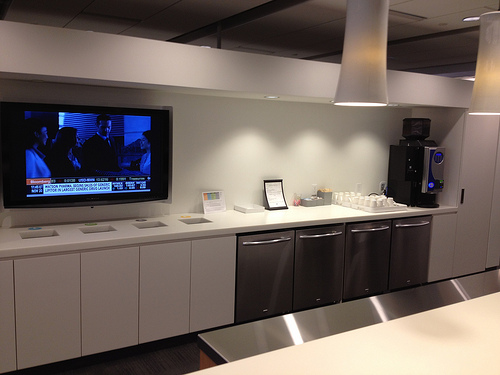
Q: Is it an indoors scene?
A: Yes, it is indoors.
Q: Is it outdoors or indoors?
A: It is indoors.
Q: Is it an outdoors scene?
A: No, it is indoors.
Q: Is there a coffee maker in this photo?
A: Yes, there is a coffee maker.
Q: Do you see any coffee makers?
A: Yes, there is a coffee maker.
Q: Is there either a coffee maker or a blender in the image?
A: Yes, there is a coffee maker.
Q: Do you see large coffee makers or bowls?
A: Yes, there is a large coffee maker.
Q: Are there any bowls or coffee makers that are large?
A: Yes, the coffee maker is large.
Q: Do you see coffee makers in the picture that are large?
A: Yes, there is a large coffee maker.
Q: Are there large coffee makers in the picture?
A: Yes, there is a large coffee maker.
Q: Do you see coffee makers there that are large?
A: Yes, there is a coffee maker that is large.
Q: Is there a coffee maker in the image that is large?
A: Yes, there is a coffee maker that is large.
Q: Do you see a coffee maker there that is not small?
A: Yes, there is a large coffee maker.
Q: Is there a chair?
A: No, there are no chairs.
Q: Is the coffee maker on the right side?
A: Yes, the coffee maker is on the right of the image.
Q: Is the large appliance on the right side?
A: Yes, the coffee maker is on the right of the image.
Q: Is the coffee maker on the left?
A: No, the coffee maker is on the right of the image.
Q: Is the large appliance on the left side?
A: No, the coffee maker is on the right of the image.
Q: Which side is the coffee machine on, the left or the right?
A: The coffee machine is on the right of the image.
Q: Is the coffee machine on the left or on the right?
A: The coffee machine is on the right of the image.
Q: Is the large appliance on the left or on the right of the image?
A: The coffee machine is on the right of the image.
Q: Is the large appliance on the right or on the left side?
A: The coffee machine is on the right of the image.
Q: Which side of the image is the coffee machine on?
A: The coffee machine is on the right of the image.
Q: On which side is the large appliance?
A: The coffee machine is on the right of the image.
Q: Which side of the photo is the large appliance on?
A: The coffee machine is on the right of the image.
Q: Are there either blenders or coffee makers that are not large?
A: No, there is a coffee maker but it is large.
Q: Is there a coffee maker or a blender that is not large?
A: No, there is a coffee maker but it is large.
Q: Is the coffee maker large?
A: Yes, the coffee maker is large.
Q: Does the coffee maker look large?
A: Yes, the coffee maker is large.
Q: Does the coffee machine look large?
A: Yes, the coffee machine is large.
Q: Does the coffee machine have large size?
A: Yes, the coffee machine is large.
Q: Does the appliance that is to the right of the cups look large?
A: Yes, the coffee machine is large.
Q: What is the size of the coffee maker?
A: The coffee maker is large.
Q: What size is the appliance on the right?
A: The coffee maker is large.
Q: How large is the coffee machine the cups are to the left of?
A: The coffee machine is large.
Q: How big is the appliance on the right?
A: The coffee machine is large.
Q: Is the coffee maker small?
A: No, the coffee maker is large.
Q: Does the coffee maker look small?
A: No, the coffee maker is large.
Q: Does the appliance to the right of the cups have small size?
A: No, the coffee maker is large.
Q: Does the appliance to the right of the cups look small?
A: No, the coffee maker is large.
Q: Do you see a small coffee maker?
A: No, there is a coffee maker but it is large.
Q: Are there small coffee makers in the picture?
A: No, there is a coffee maker but it is large.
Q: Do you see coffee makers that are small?
A: No, there is a coffee maker but it is large.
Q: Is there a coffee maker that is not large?
A: No, there is a coffee maker but it is large.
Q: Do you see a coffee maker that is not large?
A: No, there is a coffee maker but it is large.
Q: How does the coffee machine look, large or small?
A: The coffee machine is large.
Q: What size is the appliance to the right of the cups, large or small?
A: The coffee machine is large.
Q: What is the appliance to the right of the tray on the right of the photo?
A: The appliance is a coffee maker.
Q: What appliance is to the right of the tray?
A: The appliance is a coffee maker.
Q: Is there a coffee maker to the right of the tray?
A: Yes, there is a coffee maker to the right of the tray.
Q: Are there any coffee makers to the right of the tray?
A: Yes, there is a coffee maker to the right of the tray.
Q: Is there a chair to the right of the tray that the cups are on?
A: No, there is a coffee maker to the right of the tray.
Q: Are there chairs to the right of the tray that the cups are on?
A: No, there is a coffee maker to the right of the tray.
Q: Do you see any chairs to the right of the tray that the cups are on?
A: No, there is a coffee maker to the right of the tray.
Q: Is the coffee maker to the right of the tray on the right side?
A: Yes, the coffee maker is to the right of the tray.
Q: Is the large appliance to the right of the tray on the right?
A: Yes, the coffee maker is to the right of the tray.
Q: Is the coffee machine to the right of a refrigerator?
A: No, the coffee machine is to the right of the tray.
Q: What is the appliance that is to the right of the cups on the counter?
A: The appliance is a coffee maker.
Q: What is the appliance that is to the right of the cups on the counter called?
A: The appliance is a coffee maker.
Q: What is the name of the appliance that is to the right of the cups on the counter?
A: The appliance is a coffee maker.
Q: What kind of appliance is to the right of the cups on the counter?
A: The appliance is a coffee maker.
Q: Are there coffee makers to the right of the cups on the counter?
A: Yes, there is a coffee maker to the right of the cups.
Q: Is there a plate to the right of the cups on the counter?
A: No, there is a coffee maker to the right of the cups.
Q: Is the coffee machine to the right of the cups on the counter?
A: Yes, the coffee machine is to the right of the cups.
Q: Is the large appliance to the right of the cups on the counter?
A: Yes, the coffee machine is to the right of the cups.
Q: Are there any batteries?
A: No, there are no batteries.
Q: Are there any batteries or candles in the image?
A: No, there are no batteries or candles.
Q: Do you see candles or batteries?
A: No, there are no batteries or candles.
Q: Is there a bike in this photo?
A: No, there are no bikes.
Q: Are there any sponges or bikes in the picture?
A: No, there are no bikes or sponges.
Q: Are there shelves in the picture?
A: No, there are no shelves.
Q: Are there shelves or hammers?
A: No, there are no shelves or hammers.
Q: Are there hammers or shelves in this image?
A: No, there are no shelves or hammers.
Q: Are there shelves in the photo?
A: No, there are no shelves.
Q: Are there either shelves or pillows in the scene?
A: No, there are no shelves or pillows.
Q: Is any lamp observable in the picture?
A: Yes, there is a lamp.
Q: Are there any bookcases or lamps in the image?
A: Yes, there is a lamp.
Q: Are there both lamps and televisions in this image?
A: Yes, there are both a lamp and a television.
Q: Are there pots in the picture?
A: No, there are no pots.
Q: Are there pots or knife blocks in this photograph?
A: No, there are no pots or knife blocks.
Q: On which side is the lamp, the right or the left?
A: The lamp is on the right of the image.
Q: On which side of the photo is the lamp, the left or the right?
A: The lamp is on the right of the image.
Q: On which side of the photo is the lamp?
A: The lamp is on the right of the image.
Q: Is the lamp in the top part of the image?
A: Yes, the lamp is in the top of the image.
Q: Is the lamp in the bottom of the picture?
A: No, the lamp is in the top of the image.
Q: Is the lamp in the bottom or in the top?
A: The lamp is in the top of the image.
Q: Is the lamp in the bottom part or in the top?
A: The lamp is in the top of the image.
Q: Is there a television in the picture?
A: Yes, there is a television.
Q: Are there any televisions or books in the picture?
A: Yes, there is a television.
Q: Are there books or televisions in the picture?
A: Yes, there is a television.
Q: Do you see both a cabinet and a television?
A: Yes, there are both a television and a cabinet.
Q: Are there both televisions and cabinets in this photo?
A: Yes, there are both a television and a cabinet.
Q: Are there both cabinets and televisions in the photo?
A: Yes, there are both a television and a cabinet.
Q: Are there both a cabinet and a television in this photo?
A: Yes, there are both a television and a cabinet.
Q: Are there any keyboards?
A: No, there are no keyboards.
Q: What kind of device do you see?
A: The device is a television.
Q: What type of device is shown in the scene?
A: The device is a television.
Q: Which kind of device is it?
A: The device is a television.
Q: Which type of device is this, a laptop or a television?
A: This is a television.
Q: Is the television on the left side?
A: Yes, the television is on the left of the image.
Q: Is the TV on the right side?
A: No, the TV is on the left of the image.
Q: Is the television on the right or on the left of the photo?
A: The television is on the left of the image.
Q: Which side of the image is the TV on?
A: The TV is on the left of the image.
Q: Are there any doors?
A: Yes, there is a door.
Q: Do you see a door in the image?
A: Yes, there is a door.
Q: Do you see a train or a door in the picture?
A: Yes, there is a door.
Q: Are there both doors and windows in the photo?
A: No, there is a door but no windows.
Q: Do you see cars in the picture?
A: No, there are no cars.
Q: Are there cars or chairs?
A: No, there are no cars or chairs.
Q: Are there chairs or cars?
A: No, there are no cars or chairs.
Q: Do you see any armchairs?
A: No, there are no armchairs.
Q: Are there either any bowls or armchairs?
A: No, there are no armchairs or bowls.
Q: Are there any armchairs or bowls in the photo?
A: No, there are no armchairs or bowls.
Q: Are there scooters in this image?
A: No, there are no scooters.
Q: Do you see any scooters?
A: No, there are no scooters.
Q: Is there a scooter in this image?
A: No, there are no scooters.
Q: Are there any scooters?
A: No, there are no scooters.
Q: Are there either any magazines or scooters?
A: No, there are no scooters or magazines.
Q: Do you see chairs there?
A: No, there are no chairs.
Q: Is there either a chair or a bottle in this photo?
A: No, there are no chairs or bottles.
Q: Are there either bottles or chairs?
A: No, there are no chairs or bottles.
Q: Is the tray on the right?
A: Yes, the tray is on the right of the image.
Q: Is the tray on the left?
A: No, the tray is on the right of the image.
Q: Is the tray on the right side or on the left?
A: The tray is on the right of the image.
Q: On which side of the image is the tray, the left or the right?
A: The tray is on the right of the image.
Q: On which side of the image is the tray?
A: The tray is on the right of the image.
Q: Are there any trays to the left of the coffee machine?
A: Yes, there is a tray to the left of the coffee machine.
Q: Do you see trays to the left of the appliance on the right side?
A: Yes, there is a tray to the left of the coffee machine.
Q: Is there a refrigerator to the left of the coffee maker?
A: No, there is a tray to the left of the coffee maker.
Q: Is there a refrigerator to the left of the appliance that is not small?
A: No, there is a tray to the left of the coffee maker.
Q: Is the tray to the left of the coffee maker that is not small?
A: Yes, the tray is to the left of the coffee machine.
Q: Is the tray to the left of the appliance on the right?
A: Yes, the tray is to the left of the coffee machine.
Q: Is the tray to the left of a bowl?
A: No, the tray is to the left of the coffee machine.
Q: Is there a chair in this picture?
A: No, there are no chairs.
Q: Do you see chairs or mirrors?
A: No, there are no chairs or mirrors.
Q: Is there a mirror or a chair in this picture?
A: No, there are no chairs or mirrors.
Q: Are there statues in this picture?
A: No, there are no statues.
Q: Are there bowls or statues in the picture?
A: No, there are no statues or bowls.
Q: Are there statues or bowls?
A: No, there are no statues or bowls.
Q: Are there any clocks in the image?
A: No, there are no clocks.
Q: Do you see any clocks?
A: No, there are no clocks.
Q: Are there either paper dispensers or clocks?
A: No, there are no clocks or paper dispensers.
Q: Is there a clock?
A: No, there are no clocks.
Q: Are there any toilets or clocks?
A: No, there are no clocks or toilets.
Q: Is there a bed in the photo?
A: No, there are no beds.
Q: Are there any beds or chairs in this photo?
A: No, there are no beds or chairs.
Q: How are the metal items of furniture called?
A: The pieces of furniture are cabinets.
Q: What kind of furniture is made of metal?
A: The furniture is cabinets.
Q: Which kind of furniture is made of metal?
A: The furniture is cabinets.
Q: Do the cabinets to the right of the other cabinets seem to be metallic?
A: Yes, the cabinets are metallic.